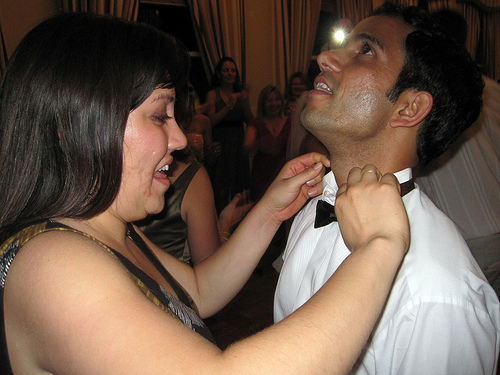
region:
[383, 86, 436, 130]
ear of a person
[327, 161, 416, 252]
hand of a person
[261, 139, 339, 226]
hand of a person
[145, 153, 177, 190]
mouth of a person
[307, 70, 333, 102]
mouth of a person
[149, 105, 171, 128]
eye of a person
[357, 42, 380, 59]
eye of a person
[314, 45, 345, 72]
nose of a person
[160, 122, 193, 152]
nose of a person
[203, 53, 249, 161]
person standing in a room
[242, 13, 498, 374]
person wearing white shirt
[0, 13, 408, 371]
lady with black hair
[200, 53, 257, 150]
person in a room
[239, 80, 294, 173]
person in a room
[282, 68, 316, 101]
person in a room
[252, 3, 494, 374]
person in a room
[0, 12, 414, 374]
person in a room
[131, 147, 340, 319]
arm of a person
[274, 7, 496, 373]
a man looking up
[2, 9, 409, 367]
a woman adjusting his bowtie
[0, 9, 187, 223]
her hair is dark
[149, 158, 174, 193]
her lips are pink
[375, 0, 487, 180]
his hair is dark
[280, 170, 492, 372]
his shirt is white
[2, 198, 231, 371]
her shirt is sleeveless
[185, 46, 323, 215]
people clapping in the background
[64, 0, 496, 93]
curtains hanging over the windows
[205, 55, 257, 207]
this woman is tall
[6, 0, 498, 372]
an image of a dance party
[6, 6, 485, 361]
a scene inside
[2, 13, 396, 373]
a woman messing with a man's collar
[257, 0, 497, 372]
a man looking up in the air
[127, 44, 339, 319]
a group of partyers in the background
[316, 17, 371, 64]
a bright light in the background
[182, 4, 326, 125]
a white curtain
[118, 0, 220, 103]
a glass window showing dark outside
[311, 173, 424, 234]
a black bowtie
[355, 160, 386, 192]
a ring on finger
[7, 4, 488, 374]
a man and a woman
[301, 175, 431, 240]
black bowtie around the neck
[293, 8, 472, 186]
head is angled up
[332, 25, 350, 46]
small, bright light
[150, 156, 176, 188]
mouth is open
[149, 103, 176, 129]
eye is looking down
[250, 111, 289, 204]
deep v neck on the dress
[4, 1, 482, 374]
woman touching the man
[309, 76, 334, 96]
row of teeth on the top of the mouth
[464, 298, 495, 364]
wrinkles on the shirt